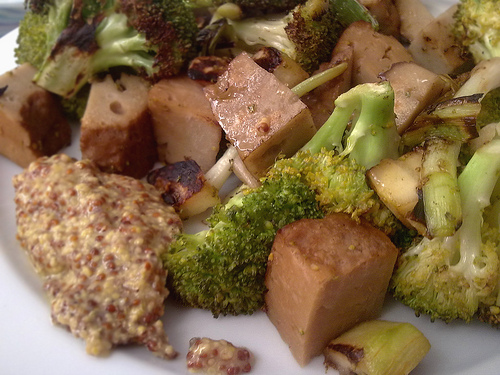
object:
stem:
[419, 129, 468, 239]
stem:
[24, 46, 113, 104]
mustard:
[108, 241, 125, 253]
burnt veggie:
[150, 157, 206, 205]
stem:
[321, 317, 431, 375]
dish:
[0, 0, 500, 372]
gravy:
[51, 149, 209, 339]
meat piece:
[0, 63, 74, 171]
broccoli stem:
[452, 141, 499, 229]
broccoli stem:
[343, 82, 399, 166]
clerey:
[321, 314, 432, 374]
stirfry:
[0, 2, 499, 374]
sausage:
[142, 77, 224, 175]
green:
[100, 50, 116, 62]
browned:
[151, 22, 169, 35]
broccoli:
[268, 0, 381, 76]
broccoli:
[384, 215, 500, 329]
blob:
[7, 152, 181, 360]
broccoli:
[161, 141, 345, 318]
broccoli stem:
[301, 82, 363, 158]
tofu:
[259, 214, 400, 368]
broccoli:
[401, 91, 499, 149]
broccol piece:
[0, 63, 72, 169]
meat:
[199, 50, 317, 182]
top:
[112, 0, 198, 24]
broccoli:
[14, 0, 196, 100]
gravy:
[26, 200, 58, 219]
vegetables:
[160, 87, 358, 322]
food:
[184, 334, 256, 374]